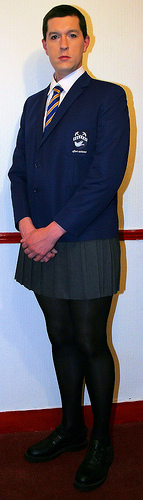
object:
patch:
[71, 129, 88, 153]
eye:
[68, 33, 77, 38]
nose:
[60, 32, 69, 50]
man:
[8, 4, 131, 490]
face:
[46, 15, 84, 75]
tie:
[44, 85, 64, 136]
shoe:
[73, 436, 113, 493]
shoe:
[24, 421, 88, 463]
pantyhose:
[34, 289, 116, 439]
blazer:
[7, 65, 130, 243]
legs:
[32, 277, 115, 440]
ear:
[83, 34, 90, 53]